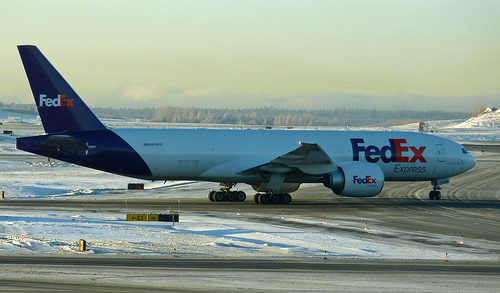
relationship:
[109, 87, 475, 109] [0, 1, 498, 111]
clouds in sky